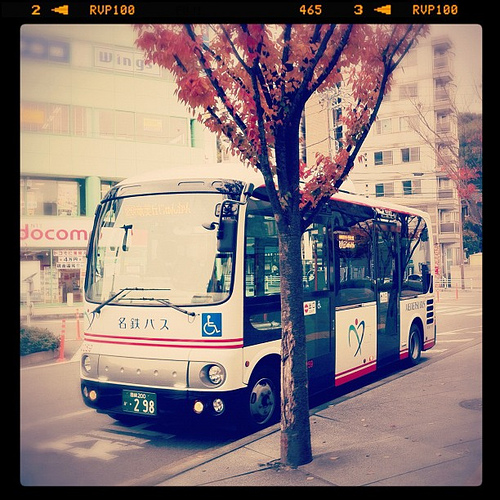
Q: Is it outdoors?
A: Yes, it is outdoors.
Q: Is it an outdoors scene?
A: Yes, it is outdoors.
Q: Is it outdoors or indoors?
A: It is outdoors.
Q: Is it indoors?
A: No, it is outdoors.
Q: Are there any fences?
A: No, there are no fences.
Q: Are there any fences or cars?
A: No, there are no fences or cars.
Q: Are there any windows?
A: Yes, there is a window.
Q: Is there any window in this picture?
A: Yes, there is a window.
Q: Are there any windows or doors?
A: Yes, there is a window.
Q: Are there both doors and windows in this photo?
A: Yes, there are both a window and a door.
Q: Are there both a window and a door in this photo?
A: Yes, there are both a window and a door.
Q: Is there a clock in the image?
A: No, there are no clocks.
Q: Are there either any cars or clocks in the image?
A: No, there are no clocks or cars.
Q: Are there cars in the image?
A: No, there are no cars.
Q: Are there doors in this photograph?
A: Yes, there is a door.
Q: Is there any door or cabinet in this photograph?
A: Yes, there is a door.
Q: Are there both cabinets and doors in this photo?
A: No, there is a door but no cabinets.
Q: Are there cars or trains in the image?
A: No, there are no cars or trains.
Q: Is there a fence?
A: No, there are no fences.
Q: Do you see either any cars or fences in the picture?
A: No, there are no fences or cars.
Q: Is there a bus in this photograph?
A: Yes, there is a bus.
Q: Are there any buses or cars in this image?
A: Yes, there is a bus.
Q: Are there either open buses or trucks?
A: Yes, there is an open bus.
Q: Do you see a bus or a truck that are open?
A: Yes, the bus is open.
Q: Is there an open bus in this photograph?
A: Yes, there is an open bus.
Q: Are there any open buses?
A: Yes, there is an open bus.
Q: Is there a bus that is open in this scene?
A: Yes, there is an open bus.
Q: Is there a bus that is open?
A: Yes, there is a bus that is open.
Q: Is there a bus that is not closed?
A: Yes, there is a open bus.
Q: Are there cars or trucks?
A: No, there are no cars or trucks.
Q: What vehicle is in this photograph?
A: The vehicle is a bus.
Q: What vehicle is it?
A: The vehicle is a bus.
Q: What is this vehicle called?
A: This is a bus.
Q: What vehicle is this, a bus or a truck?
A: This is a bus.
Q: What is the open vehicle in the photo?
A: The vehicle is a bus.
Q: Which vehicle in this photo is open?
A: The vehicle is a bus.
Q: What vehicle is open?
A: The vehicle is a bus.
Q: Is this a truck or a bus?
A: This is a bus.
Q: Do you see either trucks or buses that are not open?
A: No, there is a bus but it is open.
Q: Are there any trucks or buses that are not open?
A: No, there is a bus but it is open.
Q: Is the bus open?
A: Yes, the bus is open.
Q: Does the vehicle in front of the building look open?
A: Yes, the bus is open.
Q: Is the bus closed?
A: No, the bus is open.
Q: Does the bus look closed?
A: No, the bus is open.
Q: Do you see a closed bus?
A: No, there is a bus but it is open.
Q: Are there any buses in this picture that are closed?
A: No, there is a bus but it is open.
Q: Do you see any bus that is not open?
A: No, there is a bus but it is open.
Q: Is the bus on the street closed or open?
A: The bus is open.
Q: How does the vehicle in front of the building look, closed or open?
A: The bus is open.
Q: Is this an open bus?
A: Yes, this is an open bus.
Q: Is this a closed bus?
A: No, this is an open bus.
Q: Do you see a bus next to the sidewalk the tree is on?
A: Yes, there is a bus next to the sidewalk.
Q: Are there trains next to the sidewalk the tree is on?
A: No, there is a bus next to the sidewalk.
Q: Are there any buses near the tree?
A: Yes, there is a bus near the tree.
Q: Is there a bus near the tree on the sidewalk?
A: Yes, there is a bus near the tree.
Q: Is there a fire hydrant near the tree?
A: No, there is a bus near the tree.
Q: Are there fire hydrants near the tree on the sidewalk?
A: No, there is a bus near the tree.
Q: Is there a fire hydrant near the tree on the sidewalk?
A: No, there is a bus near the tree.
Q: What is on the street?
A: The bus is on the street.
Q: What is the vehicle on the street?
A: The vehicle is a bus.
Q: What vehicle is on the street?
A: The vehicle is a bus.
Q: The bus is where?
A: The bus is on the street.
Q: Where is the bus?
A: The bus is on the street.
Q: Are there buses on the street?
A: Yes, there is a bus on the street.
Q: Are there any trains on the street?
A: No, there is a bus on the street.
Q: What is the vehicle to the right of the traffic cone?
A: The vehicle is a bus.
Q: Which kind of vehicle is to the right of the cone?
A: The vehicle is a bus.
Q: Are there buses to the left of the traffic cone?
A: No, the bus is to the right of the traffic cone.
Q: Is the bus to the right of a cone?
A: Yes, the bus is to the right of a cone.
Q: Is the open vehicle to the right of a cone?
A: Yes, the bus is to the right of a cone.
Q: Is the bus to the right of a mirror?
A: No, the bus is to the right of a cone.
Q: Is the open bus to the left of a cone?
A: No, the bus is to the right of a cone.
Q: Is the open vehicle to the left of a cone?
A: No, the bus is to the right of a cone.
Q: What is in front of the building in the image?
A: The bus is in front of the building.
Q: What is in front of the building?
A: The bus is in front of the building.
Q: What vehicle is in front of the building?
A: The vehicle is a bus.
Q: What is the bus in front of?
A: The bus is in front of the building.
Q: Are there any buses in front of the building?
A: Yes, there is a bus in front of the building.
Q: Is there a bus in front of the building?
A: Yes, there is a bus in front of the building.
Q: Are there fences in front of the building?
A: No, there is a bus in front of the building.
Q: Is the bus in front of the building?
A: Yes, the bus is in front of the building.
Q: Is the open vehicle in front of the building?
A: Yes, the bus is in front of the building.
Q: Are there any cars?
A: No, there are no cars.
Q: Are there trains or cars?
A: No, there are no cars or trains.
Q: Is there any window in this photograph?
A: Yes, there is a window.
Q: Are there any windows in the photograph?
A: Yes, there is a window.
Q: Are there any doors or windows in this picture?
A: Yes, there is a window.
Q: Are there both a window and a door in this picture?
A: Yes, there are both a window and a door.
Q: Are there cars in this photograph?
A: No, there are no cars.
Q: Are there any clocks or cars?
A: No, there are no cars or clocks.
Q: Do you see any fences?
A: No, there are no fences.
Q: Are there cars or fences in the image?
A: No, there are no fences or cars.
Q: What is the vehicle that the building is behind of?
A: The vehicle is a bus.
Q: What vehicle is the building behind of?
A: The building is behind the bus.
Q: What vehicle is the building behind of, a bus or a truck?
A: The building is behind a bus.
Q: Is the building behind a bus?
A: Yes, the building is behind a bus.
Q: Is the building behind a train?
A: No, the building is behind a bus.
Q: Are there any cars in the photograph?
A: No, there are no cars.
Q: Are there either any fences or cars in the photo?
A: No, there are no cars or fences.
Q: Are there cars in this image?
A: No, there are no cars.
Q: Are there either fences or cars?
A: No, there are no cars or fences.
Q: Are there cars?
A: No, there are no cars.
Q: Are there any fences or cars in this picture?
A: No, there are no cars or fences.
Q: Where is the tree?
A: The tree is on the side walk.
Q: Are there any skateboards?
A: No, there are no skateboards.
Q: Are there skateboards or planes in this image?
A: No, there are no skateboards or planes.